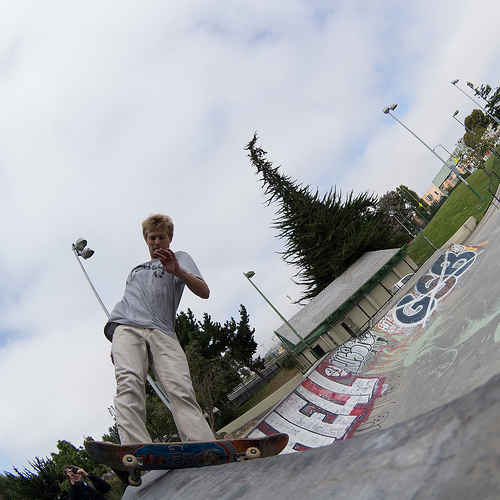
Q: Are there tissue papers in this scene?
A: No, there are no tissue papers.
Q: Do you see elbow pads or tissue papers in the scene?
A: No, there are no tissue papers or elbow pads.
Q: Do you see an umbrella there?
A: No, there are no umbrellas.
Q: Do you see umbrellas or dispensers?
A: No, there are no umbrellas or dispensers.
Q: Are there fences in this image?
A: No, there are no fences.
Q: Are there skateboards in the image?
A: Yes, there is a skateboard.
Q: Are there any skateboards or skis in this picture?
A: Yes, there is a skateboard.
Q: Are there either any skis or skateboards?
A: Yes, there is a skateboard.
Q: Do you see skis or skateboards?
A: Yes, there is a skateboard.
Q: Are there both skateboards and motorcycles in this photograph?
A: No, there is a skateboard but no motorcycles.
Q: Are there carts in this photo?
A: No, there are no carts.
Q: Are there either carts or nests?
A: No, there are no carts or nests.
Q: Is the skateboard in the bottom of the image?
A: Yes, the skateboard is in the bottom of the image.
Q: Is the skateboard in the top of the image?
A: No, the skateboard is in the bottom of the image.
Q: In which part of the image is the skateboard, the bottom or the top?
A: The skateboard is in the bottom of the image.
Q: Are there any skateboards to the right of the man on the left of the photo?
A: Yes, there is a skateboard to the right of the man.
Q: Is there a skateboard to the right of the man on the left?
A: Yes, there is a skateboard to the right of the man.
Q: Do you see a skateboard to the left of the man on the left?
A: No, the skateboard is to the right of the man.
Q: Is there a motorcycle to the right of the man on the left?
A: No, there is a skateboard to the right of the man.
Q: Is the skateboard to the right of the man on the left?
A: Yes, the skateboard is to the right of the man.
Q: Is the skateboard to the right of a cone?
A: No, the skateboard is to the right of the man.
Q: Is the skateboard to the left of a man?
A: No, the skateboard is to the right of a man.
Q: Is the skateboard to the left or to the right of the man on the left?
A: The skateboard is to the right of the man.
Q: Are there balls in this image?
A: No, there are no balls.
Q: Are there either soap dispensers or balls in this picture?
A: No, there are no balls or soap dispensers.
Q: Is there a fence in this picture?
A: No, there are no fences.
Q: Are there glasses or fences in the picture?
A: No, there are no fences or glasses.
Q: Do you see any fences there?
A: No, there are no fences.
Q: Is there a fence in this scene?
A: No, there are no fences.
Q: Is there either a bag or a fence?
A: No, there are no fences or bags.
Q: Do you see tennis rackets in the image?
A: No, there are no tennis rackets.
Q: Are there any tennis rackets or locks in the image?
A: No, there are no tennis rackets or locks.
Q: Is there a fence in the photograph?
A: No, there are no fences.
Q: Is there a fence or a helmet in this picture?
A: No, there are no fences or helmets.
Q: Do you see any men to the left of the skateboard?
A: Yes, there is a man to the left of the skateboard.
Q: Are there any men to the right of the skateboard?
A: No, the man is to the left of the skateboard.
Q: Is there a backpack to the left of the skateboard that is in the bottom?
A: No, there is a man to the left of the skateboard.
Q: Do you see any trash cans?
A: No, there are no trash cans.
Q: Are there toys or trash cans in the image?
A: No, there are no trash cans or toys.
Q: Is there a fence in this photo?
A: No, there are no fences.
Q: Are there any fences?
A: No, there are no fences.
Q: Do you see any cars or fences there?
A: No, there are no fences or cars.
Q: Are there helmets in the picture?
A: No, there are no helmets.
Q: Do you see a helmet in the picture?
A: No, there are no helmets.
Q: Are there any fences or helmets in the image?
A: No, there are no helmets or fences.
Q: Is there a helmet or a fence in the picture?
A: No, there are no helmets or fences.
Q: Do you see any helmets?
A: No, there are no helmets.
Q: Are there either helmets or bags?
A: No, there are no helmets or bags.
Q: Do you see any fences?
A: No, there are no fences.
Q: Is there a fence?
A: No, there are no fences.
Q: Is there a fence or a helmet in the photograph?
A: No, there are no fences or helmets.